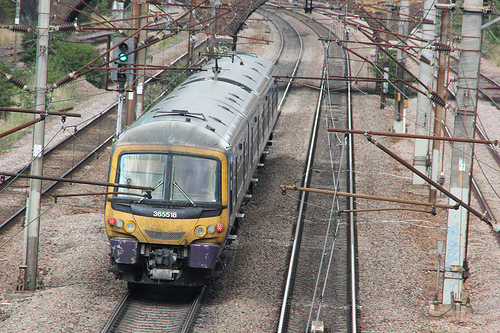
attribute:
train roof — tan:
[126, 42, 277, 204]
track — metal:
[284, 78, 367, 330]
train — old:
[102, 50, 279, 279]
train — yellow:
[99, 144, 226, 246]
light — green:
[118, 54, 128, 62]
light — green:
[108, 35, 136, 85]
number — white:
[151, 211, 180, 218]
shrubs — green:
[45, 32, 103, 88]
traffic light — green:
[117, 51, 127, 63]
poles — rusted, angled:
[325, 123, 499, 228]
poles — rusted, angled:
[3, 170, 155, 208]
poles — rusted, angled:
[314, 20, 497, 113]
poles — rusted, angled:
[2, 18, 201, 86]